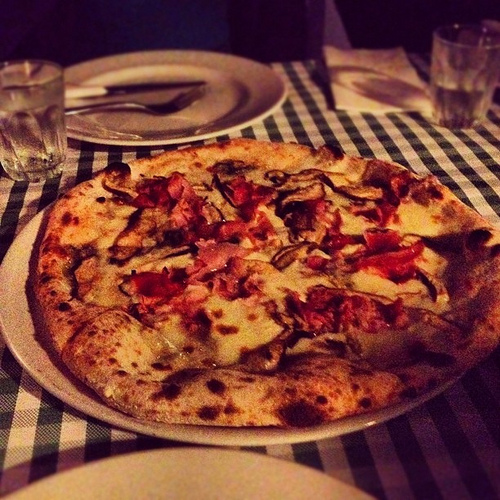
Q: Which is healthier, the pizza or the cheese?
A: The cheese is healthier than the pizza.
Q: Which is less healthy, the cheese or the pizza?
A: The pizza is less healthy than the cheese.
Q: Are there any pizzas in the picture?
A: Yes, there is a pizza.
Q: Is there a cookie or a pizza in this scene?
A: Yes, there is a pizza.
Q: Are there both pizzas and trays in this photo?
A: No, there is a pizza but no trays.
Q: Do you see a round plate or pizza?
A: Yes, there is a round pizza.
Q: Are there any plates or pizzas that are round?
A: Yes, the pizza is round.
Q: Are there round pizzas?
A: Yes, there is a round pizza.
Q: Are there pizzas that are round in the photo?
A: Yes, there is a round pizza.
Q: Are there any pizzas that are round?
A: Yes, there is a pizza that is round.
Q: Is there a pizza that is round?
A: Yes, there is a pizza that is round.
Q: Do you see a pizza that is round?
A: Yes, there is a pizza that is round.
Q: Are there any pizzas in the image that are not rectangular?
A: Yes, there is a round pizza.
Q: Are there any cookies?
A: No, there are no cookies.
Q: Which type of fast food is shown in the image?
A: The fast food is a pizza.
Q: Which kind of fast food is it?
A: The food is a pizza.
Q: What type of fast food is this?
A: This is a pizza.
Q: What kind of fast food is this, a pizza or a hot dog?
A: This is a pizza.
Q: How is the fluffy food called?
A: The food is a pizza.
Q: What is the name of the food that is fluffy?
A: The food is a pizza.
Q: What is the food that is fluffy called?
A: The food is a pizza.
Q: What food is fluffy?
A: The food is a pizza.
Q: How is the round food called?
A: The food is a pizza.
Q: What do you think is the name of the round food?
A: The food is a pizza.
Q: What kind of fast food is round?
A: The fast food is a pizza.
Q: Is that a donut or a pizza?
A: That is a pizza.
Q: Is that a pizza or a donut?
A: That is a pizza.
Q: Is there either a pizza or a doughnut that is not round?
A: No, there is a pizza but it is round.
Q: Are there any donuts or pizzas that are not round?
A: No, there is a pizza but it is round.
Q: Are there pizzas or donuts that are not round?
A: No, there is a pizza but it is round.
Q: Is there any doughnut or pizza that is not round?
A: No, there is a pizza but it is round.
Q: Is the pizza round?
A: Yes, the pizza is round.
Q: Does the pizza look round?
A: Yes, the pizza is round.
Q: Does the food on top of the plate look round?
A: Yes, the pizza is round.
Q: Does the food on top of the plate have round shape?
A: Yes, the pizza is round.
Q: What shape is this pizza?
A: The pizza is round.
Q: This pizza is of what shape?
A: The pizza is round.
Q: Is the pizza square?
A: No, the pizza is round.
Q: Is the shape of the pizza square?
A: No, the pizza is round.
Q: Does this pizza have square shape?
A: No, the pizza is round.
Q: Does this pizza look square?
A: No, the pizza is round.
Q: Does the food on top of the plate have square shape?
A: No, the pizza is round.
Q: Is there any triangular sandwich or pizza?
A: No, there is a pizza but it is round.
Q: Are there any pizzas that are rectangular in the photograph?
A: No, there is a pizza but it is round.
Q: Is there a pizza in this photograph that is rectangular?
A: No, there is a pizza but it is round.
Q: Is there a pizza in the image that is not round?
A: No, there is a pizza but it is round.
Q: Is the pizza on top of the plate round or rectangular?
A: The pizza is round.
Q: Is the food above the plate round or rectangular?
A: The pizza is round.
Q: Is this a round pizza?
A: Yes, this is a round pizza.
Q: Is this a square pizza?
A: No, this is a round pizza.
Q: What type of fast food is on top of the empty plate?
A: The food is a pizza.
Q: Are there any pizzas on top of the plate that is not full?
A: Yes, there is a pizza on top of the plate.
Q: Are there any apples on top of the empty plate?
A: No, there is a pizza on top of the plate.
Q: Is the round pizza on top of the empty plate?
A: Yes, the pizza is on top of the plate.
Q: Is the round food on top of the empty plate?
A: Yes, the pizza is on top of the plate.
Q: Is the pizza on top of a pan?
A: No, the pizza is on top of the plate.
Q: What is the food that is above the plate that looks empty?
A: The food is a pizza.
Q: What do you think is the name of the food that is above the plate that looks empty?
A: The food is a pizza.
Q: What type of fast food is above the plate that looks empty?
A: The food is a pizza.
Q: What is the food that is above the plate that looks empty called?
A: The food is a pizza.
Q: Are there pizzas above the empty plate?
A: Yes, there is a pizza above the plate.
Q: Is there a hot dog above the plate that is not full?
A: No, there is a pizza above the plate.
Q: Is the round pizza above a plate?
A: Yes, the pizza is above a plate.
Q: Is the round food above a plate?
A: Yes, the pizza is above a plate.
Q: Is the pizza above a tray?
A: No, the pizza is above a plate.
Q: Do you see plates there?
A: Yes, there is a plate.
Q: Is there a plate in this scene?
A: Yes, there is a plate.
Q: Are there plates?
A: Yes, there is a plate.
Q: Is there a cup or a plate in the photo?
A: Yes, there is a plate.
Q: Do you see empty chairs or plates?
A: Yes, there is an empty plate.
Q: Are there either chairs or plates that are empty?
A: Yes, the plate is empty.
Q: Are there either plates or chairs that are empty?
A: Yes, the plate is empty.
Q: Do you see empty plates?
A: Yes, there is an empty plate.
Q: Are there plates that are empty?
A: Yes, there is a plate that is empty.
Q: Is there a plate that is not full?
A: Yes, there is a empty plate.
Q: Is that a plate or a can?
A: That is a plate.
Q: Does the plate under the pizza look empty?
A: Yes, the plate is empty.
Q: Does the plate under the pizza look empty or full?
A: The plate is empty.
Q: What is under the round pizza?
A: The plate is under the pizza.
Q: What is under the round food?
A: The plate is under the pizza.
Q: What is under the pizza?
A: The plate is under the pizza.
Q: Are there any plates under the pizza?
A: Yes, there is a plate under the pizza.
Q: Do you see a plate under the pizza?
A: Yes, there is a plate under the pizza.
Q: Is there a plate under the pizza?
A: Yes, there is a plate under the pizza.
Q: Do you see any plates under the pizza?
A: Yes, there is a plate under the pizza.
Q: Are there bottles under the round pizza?
A: No, there is a plate under the pizza.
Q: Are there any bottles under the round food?
A: No, there is a plate under the pizza.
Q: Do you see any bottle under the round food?
A: No, there is a plate under the pizza.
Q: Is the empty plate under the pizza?
A: Yes, the plate is under the pizza.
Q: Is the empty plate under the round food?
A: Yes, the plate is under the pizza.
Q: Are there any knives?
A: Yes, there is a knife.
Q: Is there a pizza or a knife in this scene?
A: Yes, there is a knife.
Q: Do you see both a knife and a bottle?
A: No, there is a knife but no bottles.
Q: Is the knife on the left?
A: Yes, the knife is on the left of the image.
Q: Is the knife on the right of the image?
A: No, the knife is on the left of the image.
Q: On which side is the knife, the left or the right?
A: The knife is on the left of the image.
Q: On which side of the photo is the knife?
A: The knife is on the left of the image.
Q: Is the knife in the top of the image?
A: Yes, the knife is in the top of the image.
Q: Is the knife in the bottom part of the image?
A: No, the knife is in the top of the image.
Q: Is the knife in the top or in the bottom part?
A: The knife is in the top of the image.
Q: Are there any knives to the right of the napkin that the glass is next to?
A: No, the knife is to the left of the napkin.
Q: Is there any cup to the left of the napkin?
A: No, there is a knife to the left of the napkin.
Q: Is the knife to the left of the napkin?
A: Yes, the knife is to the left of the napkin.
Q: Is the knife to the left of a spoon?
A: No, the knife is to the left of the napkin.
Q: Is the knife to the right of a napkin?
A: No, the knife is to the left of a napkin.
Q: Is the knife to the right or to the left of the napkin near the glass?
A: The knife is to the left of the napkin.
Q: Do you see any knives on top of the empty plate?
A: Yes, there is a knife on top of the plate.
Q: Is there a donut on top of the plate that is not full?
A: No, there is a knife on top of the plate.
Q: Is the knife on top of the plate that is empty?
A: Yes, the knife is on top of the plate.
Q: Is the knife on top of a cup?
A: No, the knife is on top of the plate.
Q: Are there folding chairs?
A: No, there are no folding chairs.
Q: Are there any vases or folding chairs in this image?
A: No, there are no folding chairs or vases.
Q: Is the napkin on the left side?
A: No, the napkin is on the right of the image.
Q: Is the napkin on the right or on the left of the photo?
A: The napkin is on the right of the image.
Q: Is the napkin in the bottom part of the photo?
A: No, the napkin is in the top of the image.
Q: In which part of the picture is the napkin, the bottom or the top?
A: The napkin is in the top of the image.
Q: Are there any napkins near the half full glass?
A: Yes, there is a napkin near the glass.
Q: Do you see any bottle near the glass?
A: No, there is a napkin near the glass.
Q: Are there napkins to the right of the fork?
A: Yes, there is a napkin to the right of the fork.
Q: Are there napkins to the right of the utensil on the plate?
A: Yes, there is a napkin to the right of the fork.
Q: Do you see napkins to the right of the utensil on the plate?
A: Yes, there is a napkin to the right of the fork.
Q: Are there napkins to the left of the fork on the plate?
A: No, the napkin is to the right of the fork.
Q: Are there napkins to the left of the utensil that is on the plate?
A: No, the napkin is to the right of the fork.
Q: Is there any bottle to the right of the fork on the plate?
A: No, there is a napkin to the right of the fork.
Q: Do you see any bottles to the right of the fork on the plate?
A: No, there is a napkin to the right of the fork.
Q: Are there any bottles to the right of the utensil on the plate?
A: No, there is a napkin to the right of the fork.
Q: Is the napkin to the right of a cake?
A: No, the napkin is to the right of the fork.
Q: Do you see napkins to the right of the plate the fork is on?
A: Yes, there is a napkin to the right of the plate.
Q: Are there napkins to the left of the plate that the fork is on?
A: No, the napkin is to the right of the plate.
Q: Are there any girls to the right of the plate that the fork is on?
A: No, there is a napkin to the right of the plate.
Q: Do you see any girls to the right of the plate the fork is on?
A: No, there is a napkin to the right of the plate.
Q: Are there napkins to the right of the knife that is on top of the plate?
A: Yes, there is a napkin to the right of the knife.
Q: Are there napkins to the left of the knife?
A: No, the napkin is to the right of the knife.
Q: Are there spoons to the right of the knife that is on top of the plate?
A: No, there is a napkin to the right of the knife.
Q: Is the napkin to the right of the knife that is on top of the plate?
A: Yes, the napkin is to the right of the knife.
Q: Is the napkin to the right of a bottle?
A: No, the napkin is to the right of the knife.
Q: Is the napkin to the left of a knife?
A: No, the napkin is to the right of a knife.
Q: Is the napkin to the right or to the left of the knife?
A: The napkin is to the right of the knife.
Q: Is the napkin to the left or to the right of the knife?
A: The napkin is to the right of the knife.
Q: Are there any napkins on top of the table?
A: Yes, there is a napkin on top of the table.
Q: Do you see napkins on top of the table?
A: Yes, there is a napkin on top of the table.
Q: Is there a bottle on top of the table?
A: No, there is a napkin on top of the table.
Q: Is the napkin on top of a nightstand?
A: No, the napkin is on top of the table.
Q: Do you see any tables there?
A: Yes, there is a table.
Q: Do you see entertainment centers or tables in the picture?
A: Yes, there is a table.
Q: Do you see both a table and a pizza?
A: Yes, there are both a table and a pizza.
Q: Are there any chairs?
A: No, there are no chairs.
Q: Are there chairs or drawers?
A: No, there are no chairs or drawers.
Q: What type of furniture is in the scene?
A: The furniture is a table.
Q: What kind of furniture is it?
A: The piece of furniture is a table.